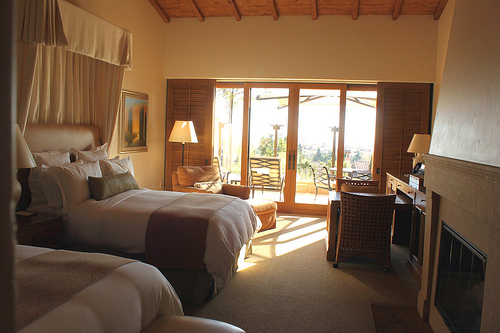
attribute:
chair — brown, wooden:
[331, 175, 400, 272]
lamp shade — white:
[15, 121, 35, 172]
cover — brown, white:
[110, 146, 237, 252]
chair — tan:
[170, 162, 251, 199]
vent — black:
[429, 217, 493, 302]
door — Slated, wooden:
[165, 72, 222, 189]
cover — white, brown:
[7, 236, 188, 331]